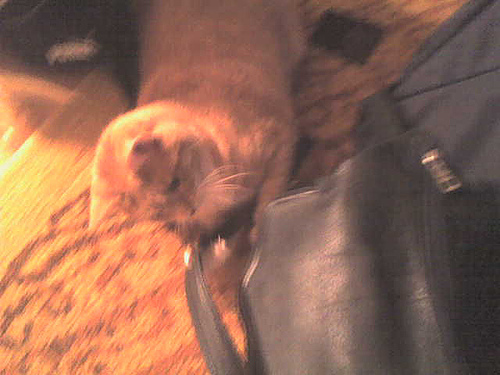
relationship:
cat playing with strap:
[87, 0, 308, 234] [178, 253, 231, 337]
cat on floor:
[97, 129, 264, 225] [55, 269, 136, 356]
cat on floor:
[87, 0, 308, 234] [4, 2, 135, 373]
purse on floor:
[186, 3, 495, 370] [6, 63, 133, 373]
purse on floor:
[186, 3, 495, 370] [4, 2, 135, 373]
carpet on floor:
[3, 129, 251, 370] [0, 0, 106, 167]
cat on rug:
[87, 0, 308, 234] [4, 105, 246, 373]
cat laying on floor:
[87, 0, 308, 234] [4, 2, 135, 373]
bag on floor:
[182, 0, 497, 374] [4, 2, 135, 373]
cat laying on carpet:
[87, 0, 308, 234] [3, 129, 251, 370]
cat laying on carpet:
[87, 0, 308, 234] [0, 145, 246, 373]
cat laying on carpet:
[87, 0, 308, 234] [14, 18, 450, 373]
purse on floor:
[184, 129, 477, 375] [4, 5, 483, 370]